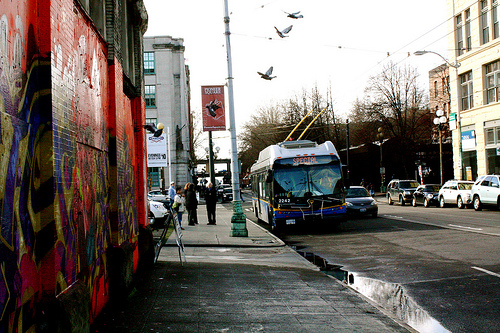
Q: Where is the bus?
A: On the street.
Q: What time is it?
A: Afternoon.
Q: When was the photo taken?
A: During the daytime.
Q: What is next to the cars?
A: Building.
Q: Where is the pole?
A: On the sidewalk.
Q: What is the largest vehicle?
A: A Streetcar.